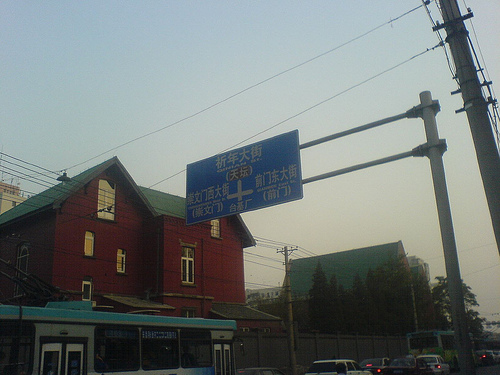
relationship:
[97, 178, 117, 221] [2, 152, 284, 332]
window adorning house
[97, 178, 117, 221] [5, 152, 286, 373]
window on house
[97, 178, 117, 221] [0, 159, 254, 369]
window on building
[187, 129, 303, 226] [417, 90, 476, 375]
blue sign mounted to post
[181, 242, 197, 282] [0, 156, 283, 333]
window on building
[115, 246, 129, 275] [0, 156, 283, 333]
window on building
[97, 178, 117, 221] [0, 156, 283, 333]
window on building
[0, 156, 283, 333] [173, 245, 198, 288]
building has window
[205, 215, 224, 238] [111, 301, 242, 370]
window on top of store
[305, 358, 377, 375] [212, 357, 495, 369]
car on road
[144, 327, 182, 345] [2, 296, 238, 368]
sign on a bus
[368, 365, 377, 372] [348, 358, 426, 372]
light on back of a car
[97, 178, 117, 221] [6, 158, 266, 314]
window on building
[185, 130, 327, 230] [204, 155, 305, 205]
blue sign with chinese writing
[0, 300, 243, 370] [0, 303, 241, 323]
bus has roof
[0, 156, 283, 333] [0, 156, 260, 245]
building has roof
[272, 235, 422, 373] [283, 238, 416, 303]
building has roof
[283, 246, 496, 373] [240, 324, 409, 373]
trees are behind fence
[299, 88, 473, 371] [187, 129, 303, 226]
post supporting blue sign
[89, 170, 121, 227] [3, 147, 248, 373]
window on building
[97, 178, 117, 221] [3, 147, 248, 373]
window on building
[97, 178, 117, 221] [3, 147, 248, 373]
window on side of building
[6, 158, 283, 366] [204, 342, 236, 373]
building has window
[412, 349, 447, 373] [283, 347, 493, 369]
car on road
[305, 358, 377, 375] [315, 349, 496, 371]
car on road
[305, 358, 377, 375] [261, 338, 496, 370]
car on road